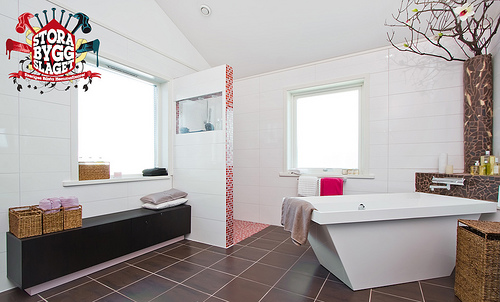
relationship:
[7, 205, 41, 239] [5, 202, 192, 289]
basket on shelf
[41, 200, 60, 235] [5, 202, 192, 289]
basket on shelf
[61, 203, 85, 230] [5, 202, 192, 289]
basket on shelf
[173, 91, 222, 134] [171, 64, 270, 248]
window on shower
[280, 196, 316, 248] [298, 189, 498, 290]
towel on tub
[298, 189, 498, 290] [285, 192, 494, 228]
tub has an edge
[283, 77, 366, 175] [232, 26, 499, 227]
window on wall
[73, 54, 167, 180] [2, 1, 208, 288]
window on wall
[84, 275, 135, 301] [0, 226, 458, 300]
line on floor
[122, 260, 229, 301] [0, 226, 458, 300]
line on floor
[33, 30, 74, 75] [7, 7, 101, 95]
words are on graphic image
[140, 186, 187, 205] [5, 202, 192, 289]
cushion on shelf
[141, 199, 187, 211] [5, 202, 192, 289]
cushion on shelf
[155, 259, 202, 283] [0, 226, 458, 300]
tile on floor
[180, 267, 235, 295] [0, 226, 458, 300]
tile on floor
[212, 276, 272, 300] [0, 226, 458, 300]
tile on floor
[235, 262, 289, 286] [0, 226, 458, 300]
tile on floor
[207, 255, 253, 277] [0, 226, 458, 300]
tile on floor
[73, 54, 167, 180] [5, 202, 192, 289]
window above shelf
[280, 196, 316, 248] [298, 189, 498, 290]
towel hanging on tub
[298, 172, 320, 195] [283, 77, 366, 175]
towel hanging below window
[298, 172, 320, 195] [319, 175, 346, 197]
towel next to towel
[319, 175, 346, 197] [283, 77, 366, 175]
towel below window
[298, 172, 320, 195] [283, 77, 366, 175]
towel below window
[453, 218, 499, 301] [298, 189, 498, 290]
hamper beside of tub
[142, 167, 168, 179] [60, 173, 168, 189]
towels are on window sill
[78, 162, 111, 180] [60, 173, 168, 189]
basket on window sill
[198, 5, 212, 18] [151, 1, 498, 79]
light on ceiling